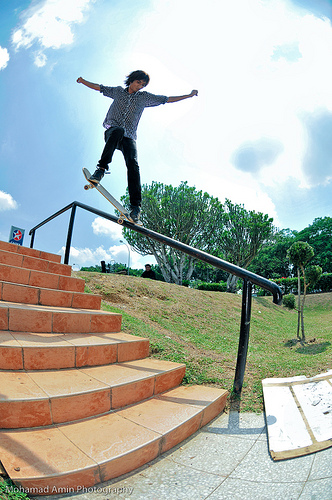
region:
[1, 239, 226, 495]
a brown outdoor stair case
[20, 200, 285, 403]
a black metal rail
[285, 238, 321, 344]
a small trimmed tree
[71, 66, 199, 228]
a male skateboarder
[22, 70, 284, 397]
a skateboarder riding rail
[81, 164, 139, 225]
a dark colored skateboard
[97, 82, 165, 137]
a blue and white shirt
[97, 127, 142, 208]
a pair of black jeans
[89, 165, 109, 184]
a black athletic shoe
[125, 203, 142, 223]
a black athletic shoe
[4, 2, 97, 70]
white clouds with a blue sky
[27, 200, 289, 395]
metal hand rail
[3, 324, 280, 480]
shadow of the metal hand rail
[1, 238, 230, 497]
red tiled stairway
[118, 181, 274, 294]
two green trees in a line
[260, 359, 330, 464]
white wood on the ground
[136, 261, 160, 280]
man wearing black is half hidden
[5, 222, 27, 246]
top of red and blue sign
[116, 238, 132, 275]
top half of the street lamp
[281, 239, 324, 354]
very small and skinny tree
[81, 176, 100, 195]
back yellow wheel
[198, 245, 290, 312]
black railing end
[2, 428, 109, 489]
lower brick step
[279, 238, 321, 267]
round tree top on branch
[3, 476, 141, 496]
mohamad amin photography written on lower left side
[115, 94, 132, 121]
buttons down center of shirt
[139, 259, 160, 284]
man under tree facing camera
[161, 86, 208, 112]
man's arm extended outward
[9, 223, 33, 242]
star inside of circle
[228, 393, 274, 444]
dark shadow of railing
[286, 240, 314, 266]
Top of tree is circular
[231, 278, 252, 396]
Black steel post for railng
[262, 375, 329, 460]
Large piece of cardboard on ground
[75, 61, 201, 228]
Skateboarder performing stunt on railing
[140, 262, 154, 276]
Man watching the skateboarder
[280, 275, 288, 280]
Small group of red flowers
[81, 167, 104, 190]
Rear part of skateboard is air-borne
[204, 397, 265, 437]
Shadow of post and railing on ground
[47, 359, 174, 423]
Orange tile stairs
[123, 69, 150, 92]
Young man has black hair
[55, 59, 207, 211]
a boy riding a skateboard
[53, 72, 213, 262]
a boy riding a skateboard on a hand rail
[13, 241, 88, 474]
a set of stairs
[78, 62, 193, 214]
a boy wearing black pants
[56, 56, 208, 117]
a boy with his arms stretched out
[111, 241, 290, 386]
a black metal hand rail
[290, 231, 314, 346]
two small trees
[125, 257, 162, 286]
a person wearing a black shirt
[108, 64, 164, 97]
a boy with brown hair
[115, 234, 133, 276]
a tall street light